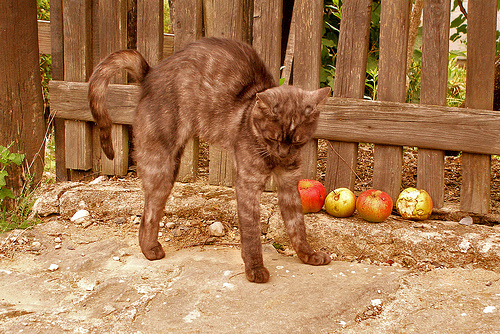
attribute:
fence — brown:
[43, 1, 498, 217]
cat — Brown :
[73, 35, 358, 280]